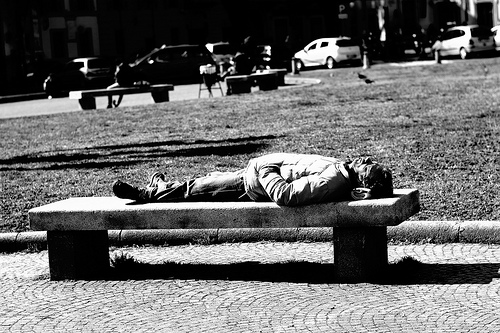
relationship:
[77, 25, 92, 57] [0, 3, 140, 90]
door on building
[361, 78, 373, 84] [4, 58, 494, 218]
bird in grass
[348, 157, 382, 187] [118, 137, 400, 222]
head on person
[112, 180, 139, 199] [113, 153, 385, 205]
foot on man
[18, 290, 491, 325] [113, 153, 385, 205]
pavement near man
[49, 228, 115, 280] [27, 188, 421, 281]
support on bench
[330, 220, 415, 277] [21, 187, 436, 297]
support on bench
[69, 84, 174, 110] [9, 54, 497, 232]
bench on park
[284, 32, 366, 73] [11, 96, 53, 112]
car parked on road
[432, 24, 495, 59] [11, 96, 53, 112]
car parked on road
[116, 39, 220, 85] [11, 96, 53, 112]
car parked on road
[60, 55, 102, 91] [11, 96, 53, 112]
car parked on road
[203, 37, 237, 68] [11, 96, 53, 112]
car parked on road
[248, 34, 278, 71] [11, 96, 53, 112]
car parked on road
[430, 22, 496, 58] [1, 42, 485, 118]
car parked on road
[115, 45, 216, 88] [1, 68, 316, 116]
car driving on road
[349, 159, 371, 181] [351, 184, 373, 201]
head on top of cloth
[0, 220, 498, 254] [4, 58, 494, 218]
curb separate grass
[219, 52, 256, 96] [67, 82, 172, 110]
person sitting on bench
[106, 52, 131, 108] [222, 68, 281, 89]
person sitting on bench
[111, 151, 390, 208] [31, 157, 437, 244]
man lying on bench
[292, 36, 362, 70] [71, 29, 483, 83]
car parked on parking lot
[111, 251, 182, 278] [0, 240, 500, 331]
weeds growing though concrete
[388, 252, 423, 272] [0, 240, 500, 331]
weeds growing though concrete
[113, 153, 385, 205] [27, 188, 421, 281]
man lying down bench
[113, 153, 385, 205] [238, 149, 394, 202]
man wearing jacket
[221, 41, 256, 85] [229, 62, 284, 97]
person sitting down on bench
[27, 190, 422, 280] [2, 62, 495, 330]
bench on park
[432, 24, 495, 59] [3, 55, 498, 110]
car parked on street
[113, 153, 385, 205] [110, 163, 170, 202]
man wearing shoes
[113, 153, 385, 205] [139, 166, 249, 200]
man wearing jean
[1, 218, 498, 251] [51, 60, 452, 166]
curve in front of grass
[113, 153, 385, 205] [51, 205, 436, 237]
man reclining on bench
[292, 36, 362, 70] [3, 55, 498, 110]
car parked on street